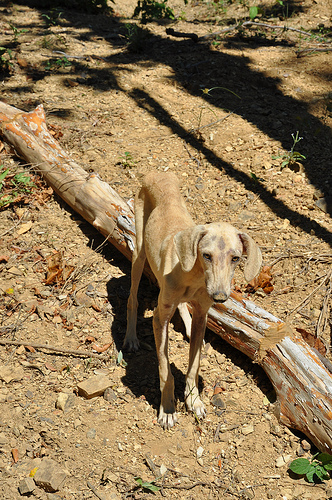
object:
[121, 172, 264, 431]
dog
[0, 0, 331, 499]
ground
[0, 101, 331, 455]
log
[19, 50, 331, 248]
shadows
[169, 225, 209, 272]
ear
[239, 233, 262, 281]
ear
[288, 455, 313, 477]
leaves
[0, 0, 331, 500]
daytime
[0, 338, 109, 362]
stick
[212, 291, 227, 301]
dirt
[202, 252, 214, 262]
sad eyes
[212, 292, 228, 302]
nose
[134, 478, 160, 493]
leaf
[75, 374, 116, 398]
brick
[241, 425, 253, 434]
rock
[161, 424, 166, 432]
nail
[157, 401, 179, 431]
foot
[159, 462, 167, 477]
leaf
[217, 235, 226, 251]
gray spot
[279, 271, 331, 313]
twigs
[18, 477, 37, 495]
rock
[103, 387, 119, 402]
rock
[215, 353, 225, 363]
rock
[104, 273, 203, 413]
shadow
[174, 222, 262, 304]
head